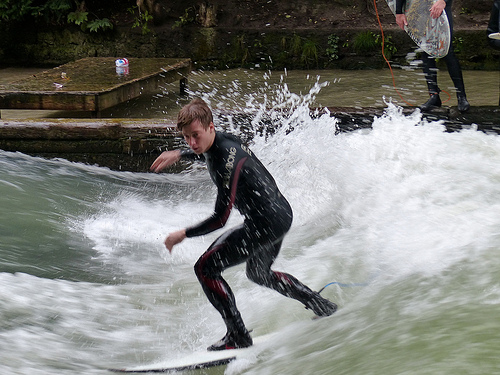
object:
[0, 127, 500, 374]
water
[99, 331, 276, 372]
surfboard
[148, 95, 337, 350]
person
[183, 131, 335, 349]
wetsuit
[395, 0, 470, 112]
person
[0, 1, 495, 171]
background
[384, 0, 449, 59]
surfboard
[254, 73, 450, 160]
splash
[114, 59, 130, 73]
bottle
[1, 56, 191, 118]
bench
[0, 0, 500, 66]
wall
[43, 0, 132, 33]
plants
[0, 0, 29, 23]
tree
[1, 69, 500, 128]
pavement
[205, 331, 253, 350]
shoe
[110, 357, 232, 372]
edge